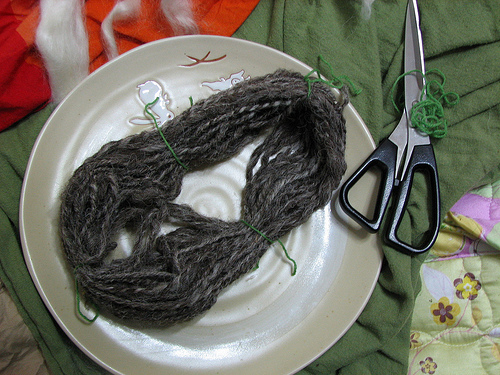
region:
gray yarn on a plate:
[57, 70, 345, 326]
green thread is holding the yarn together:
[56, 66, 356, 334]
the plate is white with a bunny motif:
[25, 33, 387, 373]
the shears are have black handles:
[340, 0, 445, 255]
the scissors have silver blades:
[337, 0, 440, 250]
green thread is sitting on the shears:
[381, 60, 458, 146]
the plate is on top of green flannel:
[2, 5, 420, 372]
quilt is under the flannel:
[412, 186, 492, 372]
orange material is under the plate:
[5, 1, 251, 122]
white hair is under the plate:
[32, 2, 376, 105]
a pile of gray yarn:
[52, 73, 367, 315]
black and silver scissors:
[337, 0, 454, 257]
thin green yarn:
[386, 64, 459, 141]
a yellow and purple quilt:
[409, 187, 499, 373]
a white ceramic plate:
[17, 25, 396, 373]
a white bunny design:
[114, 66, 194, 143]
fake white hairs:
[32, 0, 233, 135]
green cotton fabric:
[270, 0, 497, 136]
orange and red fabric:
[0, 0, 270, 170]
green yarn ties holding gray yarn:
[261, 60, 363, 145]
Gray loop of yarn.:
[48, 85, 358, 335]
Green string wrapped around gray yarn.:
[85, 78, 368, 363]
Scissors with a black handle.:
[325, 74, 473, 275]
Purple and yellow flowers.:
[420, 255, 491, 350]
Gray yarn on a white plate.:
[82, 110, 377, 373]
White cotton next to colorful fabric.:
[1, 5, 188, 105]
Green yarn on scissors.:
[370, 62, 467, 221]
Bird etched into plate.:
[135, 32, 262, 80]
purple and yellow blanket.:
[393, 186, 487, 366]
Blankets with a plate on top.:
[56, 65, 482, 370]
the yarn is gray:
[76, 52, 373, 330]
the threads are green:
[299, 59, 359, 112]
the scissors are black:
[382, 5, 479, 305]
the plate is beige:
[46, 33, 389, 373]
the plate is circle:
[25, 35, 370, 370]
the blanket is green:
[304, 15, 429, 164]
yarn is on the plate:
[77, 55, 334, 313]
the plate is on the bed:
[9, 22, 414, 374]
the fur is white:
[33, 3, 118, 91]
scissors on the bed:
[358, 7, 470, 308]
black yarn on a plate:
[29, 82, 379, 281]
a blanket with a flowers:
[405, 200, 499, 367]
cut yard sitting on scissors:
[401, 107, 471, 154]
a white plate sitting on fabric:
[43, 100, 389, 365]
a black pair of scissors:
[333, 0, 476, 252]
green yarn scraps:
[232, 201, 320, 288]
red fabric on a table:
[11, 0, 312, 105]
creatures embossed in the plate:
[103, 85, 193, 132]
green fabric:
[318, 12, 426, 80]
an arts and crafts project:
[26, 0, 475, 331]